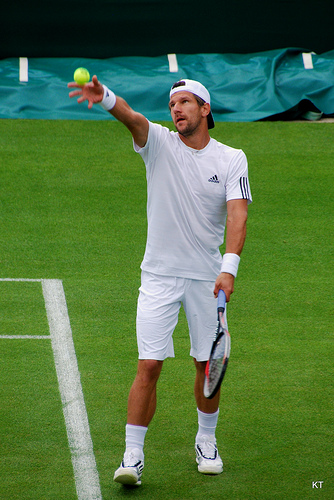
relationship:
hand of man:
[62, 73, 109, 106] [61, 53, 257, 498]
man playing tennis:
[61, 53, 257, 498] [56, 53, 297, 491]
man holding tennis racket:
[61, 53, 257, 498] [194, 289, 246, 402]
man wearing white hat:
[61, 53, 257, 498] [166, 77, 214, 103]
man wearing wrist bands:
[61, 53, 257, 498] [218, 247, 248, 281]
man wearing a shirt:
[61, 53, 257, 498] [125, 115, 256, 287]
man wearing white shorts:
[61, 53, 257, 498] [130, 271, 237, 366]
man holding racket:
[61, 53, 257, 498] [194, 289, 246, 402]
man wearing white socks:
[61, 53, 257, 498] [122, 413, 225, 445]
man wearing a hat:
[61, 53, 257, 498] [166, 77, 214, 103]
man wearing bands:
[61, 53, 257, 498] [218, 247, 248, 281]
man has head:
[61, 53, 257, 498] [144, 72, 238, 170]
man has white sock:
[61, 53, 257, 498] [122, 413, 225, 445]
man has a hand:
[61, 53, 257, 498] [60, 74, 119, 121]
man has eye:
[61, 53, 257, 498] [169, 96, 192, 110]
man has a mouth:
[61, 53, 257, 498] [169, 111, 191, 129]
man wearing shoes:
[61, 53, 257, 498] [111, 440, 229, 491]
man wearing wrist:
[61, 53, 257, 498] [218, 247, 248, 281]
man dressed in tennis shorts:
[61, 53, 257, 498] [130, 271, 237, 366]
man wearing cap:
[61, 53, 257, 498] [166, 77, 214, 103]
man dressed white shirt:
[61, 53, 257, 498] [125, 115, 256, 287]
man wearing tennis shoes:
[61, 53, 257, 498] [111, 440, 229, 491]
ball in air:
[71, 61, 94, 93] [6, 8, 327, 496]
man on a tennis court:
[61, 53, 257, 498] [6, 8, 327, 496]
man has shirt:
[61, 53, 257, 498] [125, 115, 256, 287]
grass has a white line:
[5, 110, 330, 490] [5, 264, 103, 500]